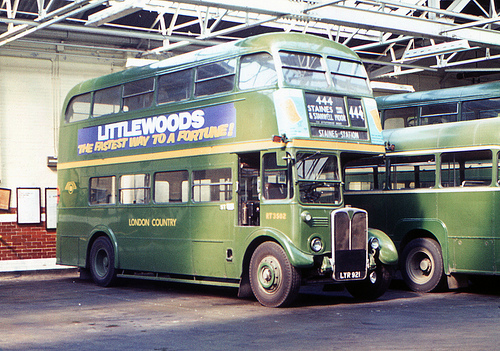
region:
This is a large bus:
[38, 61, 383, 345]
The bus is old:
[115, 47, 394, 269]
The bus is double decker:
[140, 74, 231, 176]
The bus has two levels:
[144, 71, 337, 338]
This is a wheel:
[215, 216, 303, 288]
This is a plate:
[335, 247, 389, 297]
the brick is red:
[21, 216, 33, 244]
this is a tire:
[246, 280, 285, 320]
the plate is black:
[320, 258, 403, 286]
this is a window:
[100, 178, 160, 214]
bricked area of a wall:
[0, 217, 66, 261]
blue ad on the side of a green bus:
[68, 95, 249, 151]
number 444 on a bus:
[313, 90, 337, 107]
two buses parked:
[50, 23, 499, 310]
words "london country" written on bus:
[123, 210, 183, 230]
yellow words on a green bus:
[121, 208, 183, 235]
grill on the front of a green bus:
[327, 203, 379, 288]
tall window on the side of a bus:
[235, 150, 266, 230]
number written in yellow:
[261, 209, 288, 222]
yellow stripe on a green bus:
[53, 125, 387, 166]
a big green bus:
[21, 57, 412, 349]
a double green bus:
[34, 37, 496, 346]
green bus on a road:
[44, 48, 455, 341]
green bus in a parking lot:
[40, 30, 480, 350]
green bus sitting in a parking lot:
[62, 34, 497, 301]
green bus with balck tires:
[30, 33, 421, 350]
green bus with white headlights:
[32, 35, 462, 346]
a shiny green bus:
[61, 23, 481, 347]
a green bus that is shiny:
[47, 23, 497, 329]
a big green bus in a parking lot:
[35, 27, 416, 307]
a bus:
[53, 31, 403, 307]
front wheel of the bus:
[251, 243, 298, 307]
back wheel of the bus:
[86, 233, 109, 278]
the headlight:
[311, 234, 322, 254]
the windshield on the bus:
[294, 154, 344, 201]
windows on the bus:
[96, 174, 222, 204]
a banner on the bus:
[77, 108, 247, 149]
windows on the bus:
[69, 70, 240, 111]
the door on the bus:
[235, 160, 260, 222]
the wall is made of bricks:
[11, 225, 59, 257]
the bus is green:
[47, 33, 377, 305]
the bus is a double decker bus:
[47, 62, 492, 268]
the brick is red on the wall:
[11, 225, 68, 275]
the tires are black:
[74, 212, 316, 323]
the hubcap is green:
[245, 256, 306, 302]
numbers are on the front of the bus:
[316, 250, 396, 287]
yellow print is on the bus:
[87, 194, 259, 244]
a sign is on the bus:
[70, 113, 314, 161]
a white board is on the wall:
[12, 172, 59, 249]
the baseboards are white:
[6, 234, 62, 301]